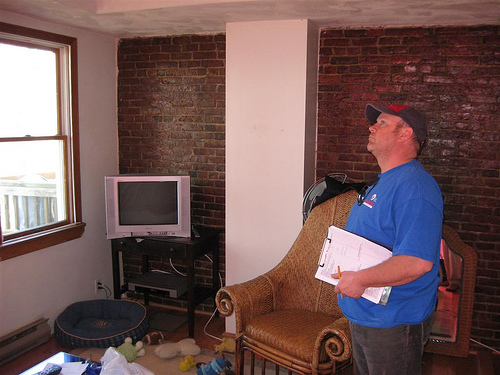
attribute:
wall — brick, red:
[120, 26, 497, 349]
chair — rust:
[202, 165, 428, 369]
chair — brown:
[210, 186, 370, 363]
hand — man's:
[329, 253, 384, 319]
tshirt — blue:
[334, 163, 442, 325]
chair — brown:
[212, 188, 400, 370]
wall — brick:
[324, 36, 494, 267]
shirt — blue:
[337, 154, 442, 328]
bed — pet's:
[50, 293, 151, 349]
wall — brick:
[119, 35, 250, 302]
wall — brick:
[319, 20, 497, 335]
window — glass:
[2, 107, 61, 214]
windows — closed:
[8, 42, 75, 237]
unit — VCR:
[125, 262, 197, 302]